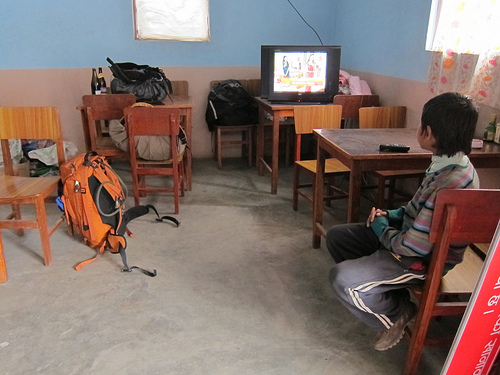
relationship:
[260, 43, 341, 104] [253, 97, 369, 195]
tv on table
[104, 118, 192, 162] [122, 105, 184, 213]
sack on chair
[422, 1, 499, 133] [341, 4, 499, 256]
window on side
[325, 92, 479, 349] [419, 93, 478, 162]
boy has hair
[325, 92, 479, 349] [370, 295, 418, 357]
boy wearing shoes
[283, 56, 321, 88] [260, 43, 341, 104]
women on tv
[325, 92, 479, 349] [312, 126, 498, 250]
boy at table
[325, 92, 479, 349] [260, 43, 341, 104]
boy watching tv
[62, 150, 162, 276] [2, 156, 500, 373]
backpack on floor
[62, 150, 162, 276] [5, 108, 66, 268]
backpack next to chair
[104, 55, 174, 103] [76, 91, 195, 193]
backpack on table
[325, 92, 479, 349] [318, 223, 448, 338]
boy wearing sweatpants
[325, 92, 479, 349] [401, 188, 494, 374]
boy sitting in chair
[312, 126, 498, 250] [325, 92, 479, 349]
table in front of boy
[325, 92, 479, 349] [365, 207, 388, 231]
boy's hands together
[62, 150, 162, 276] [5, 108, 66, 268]
backpack against chair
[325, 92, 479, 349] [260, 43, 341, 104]
boy facing tv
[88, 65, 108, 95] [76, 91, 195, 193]
bottles on table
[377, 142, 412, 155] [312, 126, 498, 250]
remote on table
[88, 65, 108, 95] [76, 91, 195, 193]
beer bottles on table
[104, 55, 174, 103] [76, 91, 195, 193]
bag on table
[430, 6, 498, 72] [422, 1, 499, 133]
light through window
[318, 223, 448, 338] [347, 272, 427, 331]
pants have stipes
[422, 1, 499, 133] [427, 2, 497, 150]
curtain in front of window